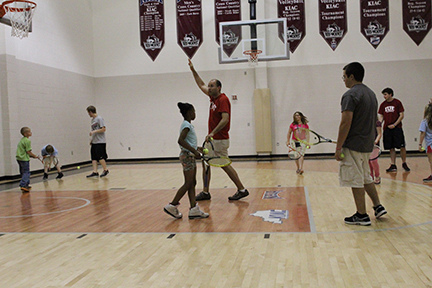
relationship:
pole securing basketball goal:
[249, 0, 258, 57] [215, 17, 289, 63]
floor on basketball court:
[2, 151, 429, 285] [0, 16, 430, 284]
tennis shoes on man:
[344, 201, 387, 225] [337, 61, 384, 225]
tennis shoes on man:
[163, 200, 208, 219] [185, 59, 247, 201]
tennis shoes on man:
[296, 166, 302, 173] [185, 59, 247, 201]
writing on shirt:
[382, 104, 394, 113] [378, 97, 405, 129]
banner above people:
[138, 0, 164, 61] [16, 57, 431, 226]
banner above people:
[176, 0, 203, 59] [16, 57, 431, 226]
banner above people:
[319, 0, 347, 48] [16, 57, 431, 226]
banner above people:
[360, 0, 388, 48] [16, 57, 431, 226]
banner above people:
[402, 0, 430, 46] [16, 57, 431, 226]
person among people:
[377, 87, 410, 172] [16, 57, 431, 226]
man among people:
[189, 59, 250, 201] [16, 57, 431, 226]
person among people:
[165, 101, 209, 223] [16, 57, 431, 226]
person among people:
[85, 105, 108, 178] [16, 57, 431, 226]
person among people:
[288, 111, 305, 175] [16, 57, 431, 226]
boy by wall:
[13, 127, 42, 194] [0, 4, 95, 175]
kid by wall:
[39, 143, 63, 180] [0, 4, 95, 175]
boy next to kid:
[13, 127, 42, 194] [39, 143, 63, 180]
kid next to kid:
[39, 143, 63, 180] [39, 143, 64, 180]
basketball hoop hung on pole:
[232, 32, 285, 70] [245, 6, 265, 62]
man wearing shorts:
[189, 59, 250, 201] [202, 130, 237, 178]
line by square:
[262, 231, 272, 241] [0, 188, 313, 234]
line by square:
[165, 233, 176, 240] [0, 188, 313, 234]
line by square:
[76, 233, 90, 240] [0, 188, 313, 234]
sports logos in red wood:
[208, 192, 297, 269] [2, 196, 332, 228]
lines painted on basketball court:
[6, 193, 105, 230] [142, 223, 301, 279]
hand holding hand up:
[184, 56, 193, 65] [164, 87, 202, 142]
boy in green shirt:
[13, 119, 40, 191] [13, 134, 33, 160]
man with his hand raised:
[185, 59, 247, 201] [194, 97, 211, 106]